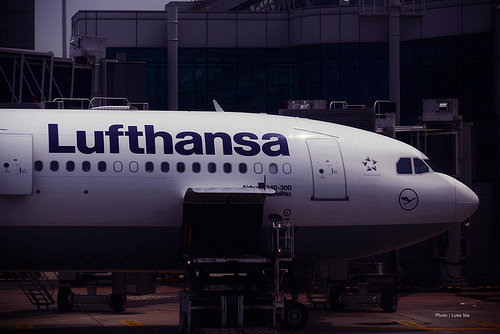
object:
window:
[81, 160, 91, 172]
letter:
[144, 124, 174, 153]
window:
[50, 160, 59, 172]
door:
[306, 137, 348, 201]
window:
[160, 160, 169, 173]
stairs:
[33, 302, 54, 305]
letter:
[261, 132, 290, 157]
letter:
[204, 132, 232, 155]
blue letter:
[105, 124, 124, 153]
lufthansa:
[48, 123, 291, 156]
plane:
[0, 109, 479, 330]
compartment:
[183, 186, 278, 258]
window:
[144, 161, 155, 173]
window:
[207, 162, 218, 173]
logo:
[399, 188, 419, 212]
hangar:
[0, 1, 499, 333]